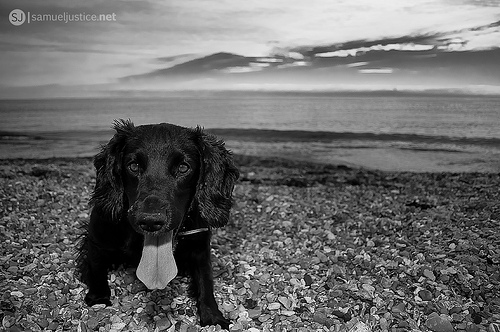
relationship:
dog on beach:
[80, 118, 238, 327] [3, 136, 499, 332]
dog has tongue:
[80, 118, 238, 327] [133, 229, 178, 288]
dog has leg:
[80, 118, 238, 327] [185, 240, 231, 330]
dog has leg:
[80, 118, 238, 327] [82, 241, 111, 308]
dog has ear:
[80, 118, 238, 327] [194, 129, 240, 225]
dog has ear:
[80, 118, 238, 327] [91, 124, 132, 224]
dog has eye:
[80, 118, 238, 327] [173, 162, 190, 177]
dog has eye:
[80, 118, 238, 327] [126, 162, 147, 176]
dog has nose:
[80, 118, 238, 327] [137, 213, 170, 233]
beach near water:
[3, 136, 499, 332] [1, 93, 500, 142]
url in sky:
[9, 9, 116, 28] [3, 0, 475, 90]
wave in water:
[10, 125, 498, 148] [1, 93, 500, 142]